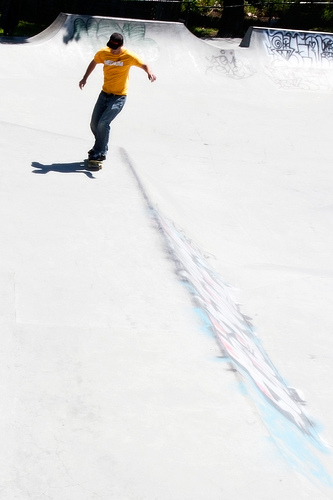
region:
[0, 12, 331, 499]
The skateboard surface is white.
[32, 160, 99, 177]
A shadow is on the ground.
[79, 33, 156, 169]
A man is on a skateboard.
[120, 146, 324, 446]
Dark markings are on a white surface.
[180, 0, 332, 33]
Green is behind a curb.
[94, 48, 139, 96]
A man is wearing a yellow shirt.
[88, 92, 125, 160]
A man is wearing blue pants.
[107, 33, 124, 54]
A head is wearing a black hat.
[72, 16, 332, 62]
Markings are on a white surface.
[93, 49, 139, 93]
A yellow shirt has a white logo on it.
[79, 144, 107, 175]
skateboard underneath man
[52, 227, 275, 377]
white ramp pointing downward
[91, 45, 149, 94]
bright yellow man's shirt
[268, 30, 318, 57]
design on right wall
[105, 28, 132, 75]
black hat on man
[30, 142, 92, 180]
black shadow on man on ground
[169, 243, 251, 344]
design on floor of ramp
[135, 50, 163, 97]
man's outstretched left arm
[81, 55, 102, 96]
man's outstretched right arm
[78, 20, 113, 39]
green design on left wall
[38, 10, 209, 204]
he is skateboarding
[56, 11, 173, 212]
he is riding is skateboard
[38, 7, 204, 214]
he is in a skatepark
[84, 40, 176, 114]
he is wearing a yellow tee shirt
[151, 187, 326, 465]
blue, white, and red graffiti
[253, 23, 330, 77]
black and white graffiti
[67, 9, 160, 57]
there is green graffiti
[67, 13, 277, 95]
there is graffiti on the ramp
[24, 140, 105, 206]
here is his shadow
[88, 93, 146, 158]
he is wearing blue jeans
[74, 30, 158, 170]
Man riding a skateboard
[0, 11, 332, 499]
Large skate park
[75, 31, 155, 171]
Man riding a skateboard in a skate park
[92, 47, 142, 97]
Short sleeved yellow shirt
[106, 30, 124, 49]
Black baseball cap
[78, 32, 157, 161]
Man wearing a yellow shirt and blue jeans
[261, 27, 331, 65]
Black and white spray paint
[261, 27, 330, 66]
Graffiti on a skating ramp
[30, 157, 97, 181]
Shadow of a man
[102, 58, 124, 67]
White graphic on a shirt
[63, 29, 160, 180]
A man is skateboarding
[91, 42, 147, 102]
Man is wearing a yellow shirt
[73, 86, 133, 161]
Man is wearing jeans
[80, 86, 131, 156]
The man's jeans are blue in color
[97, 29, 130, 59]
Man is wearing a black cap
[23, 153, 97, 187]
Man is casting a shadow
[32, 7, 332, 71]
Two skating ramps in the background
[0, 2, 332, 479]
Photo was taken outdoors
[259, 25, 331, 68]
Skating ramp has graffiti on it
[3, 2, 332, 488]
Photo was taken in the daytime